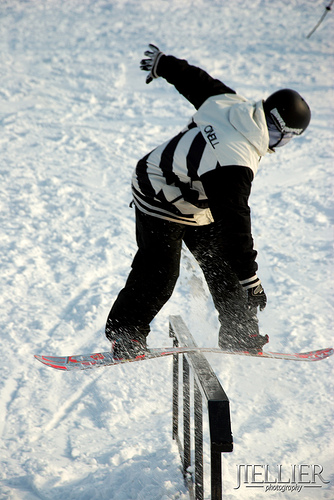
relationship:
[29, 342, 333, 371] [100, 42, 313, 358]
snowboard under person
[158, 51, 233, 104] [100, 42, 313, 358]
arm of person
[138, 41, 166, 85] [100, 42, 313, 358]
hand of person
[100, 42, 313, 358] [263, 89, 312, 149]
person wearing helmet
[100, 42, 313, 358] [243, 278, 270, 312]
person wearing glove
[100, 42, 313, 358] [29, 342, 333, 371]
person riding snowboard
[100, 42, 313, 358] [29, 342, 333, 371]
person standing on snowboard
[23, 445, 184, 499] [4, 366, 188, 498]
shadow on ground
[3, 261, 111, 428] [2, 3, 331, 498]
tracks on snow